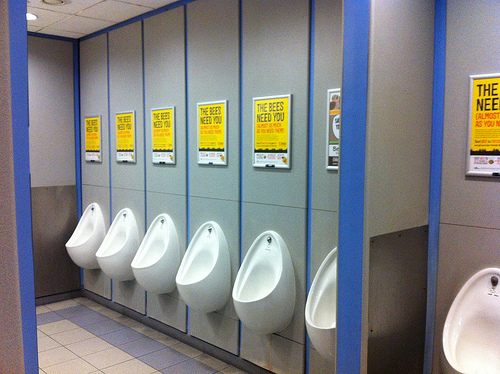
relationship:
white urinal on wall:
[64, 202, 108, 272] [75, 0, 499, 373]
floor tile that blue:
[35, 296, 246, 372] [37, 304, 222, 373]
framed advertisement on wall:
[251, 93, 292, 171] [75, 0, 499, 373]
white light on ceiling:
[26, 13, 37, 22] [26, 0, 179, 39]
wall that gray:
[75, 0, 499, 373] [251, 6, 300, 76]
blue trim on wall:
[336, 1, 372, 373] [75, 0, 499, 373]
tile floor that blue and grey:
[35, 296, 246, 372] [54, 304, 108, 348]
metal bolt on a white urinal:
[90, 204, 95, 212] [64, 202, 108, 272]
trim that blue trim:
[336, 1, 372, 373] [336, 1, 372, 373]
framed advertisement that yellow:
[251, 93, 292, 171] [256, 100, 287, 148]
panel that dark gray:
[239, 1, 311, 373] [251, 6, 300, 76]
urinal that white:
[64, 202, 108, 272] [77, 243, 90, 256]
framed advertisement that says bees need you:
[251, 93, 292, 171] [256, 101, 286, 121]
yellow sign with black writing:
[251, 93, 292, 171] [256, 101, 286, 121]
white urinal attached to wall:
[64, 202, 108, 272] [75, 0, 499, 373]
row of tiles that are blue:
[35, 296, 246, 372] [37, 304, 222, 373]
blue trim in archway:
[336, 1, 372, 373] [2, 0, 447, 367]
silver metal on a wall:
[368, 225, 430, 374] [333, 0, 448, 373]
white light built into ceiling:
[26, 13, 37, 22] [26, 0, 179, 39]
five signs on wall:
[86, 93, 294, 169] [75, 0, 499, 373]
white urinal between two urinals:
[175, 221, 232, 315] [129, 211, 298, 333]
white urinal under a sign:
[64, 202, 108, 272] [83, 113, 104, 164]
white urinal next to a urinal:
[64, 202, 108, 272] [94, 206, 141, 279]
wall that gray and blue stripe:
[75, 0, 499, 373] [133, 32, 250, 89]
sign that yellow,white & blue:
[83, 113, 104, 164] [86, 120, 99, 158]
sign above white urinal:
[83, 113, 104, 164] [64, 202, 108, 272]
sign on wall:
[83, 113, 104, 164] [75, 0, 499, 373]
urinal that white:
[94, 206, 141, 279] [112, 256, 125, 270]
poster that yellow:
[83, 113, 104, 164] [86, 118, 97, 148]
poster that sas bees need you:
[251, 93, 292, 171] [256, 101, 286, 121]